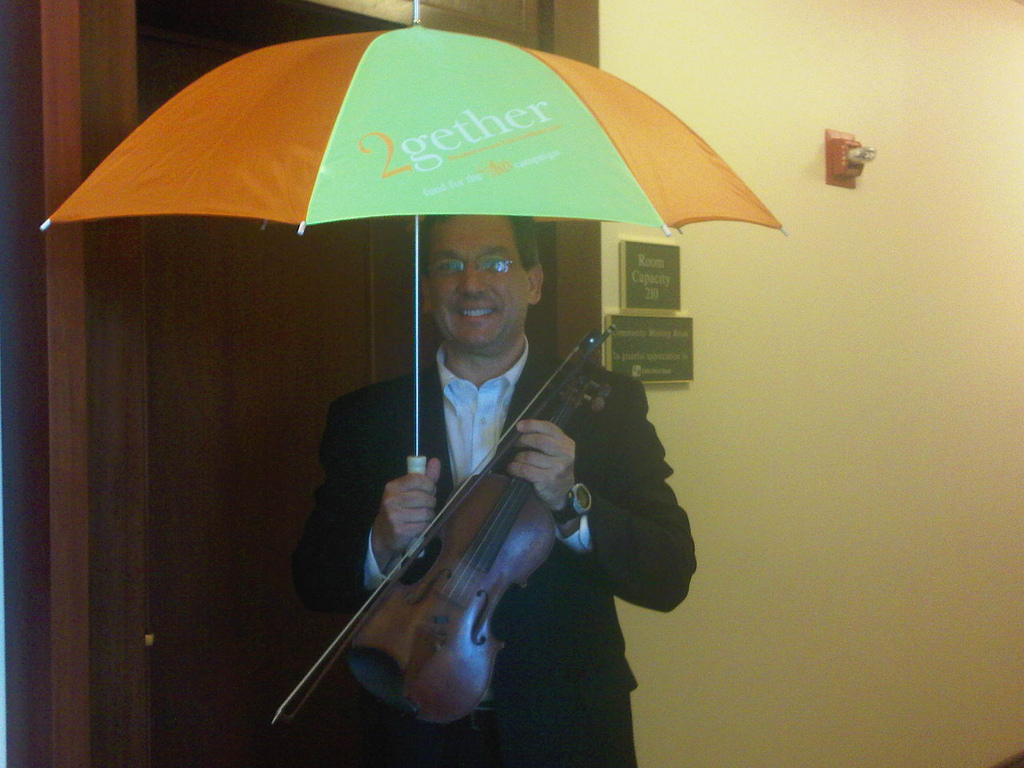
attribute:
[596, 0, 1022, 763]
wall — yellow 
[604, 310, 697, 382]
sign — black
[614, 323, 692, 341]
lettering — gold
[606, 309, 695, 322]
frame — gold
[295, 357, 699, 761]
jacket — black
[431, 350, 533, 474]
shirt — white 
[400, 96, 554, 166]
text — white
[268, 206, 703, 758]
man — posing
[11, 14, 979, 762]
building —  side 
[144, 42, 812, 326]
umbrella — green, orange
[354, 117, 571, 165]
letters — orange, white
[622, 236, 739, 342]
sign — black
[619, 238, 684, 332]
lettering — gold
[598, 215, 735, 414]
frame — gold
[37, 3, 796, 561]
umbrella —  tan,  Orange , open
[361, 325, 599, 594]
shirt — white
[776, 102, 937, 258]
fire alarm — red, clear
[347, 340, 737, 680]
violin — carved, wooden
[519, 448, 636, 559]
watch — black, grey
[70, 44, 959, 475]
umbrella — orange, light green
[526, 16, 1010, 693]
wall — beige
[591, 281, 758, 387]
plaque — black, gold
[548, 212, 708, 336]
plaque — gold, black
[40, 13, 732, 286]
umbrella — orange, green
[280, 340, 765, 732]
blazer — black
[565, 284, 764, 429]
placard — black, gold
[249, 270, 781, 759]
violin — brown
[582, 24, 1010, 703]
wall — yellow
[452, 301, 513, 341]
teeth — white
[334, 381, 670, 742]
violin — stringed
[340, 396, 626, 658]
violin — string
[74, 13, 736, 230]
umbrella — orange, green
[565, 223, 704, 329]
plate — black, square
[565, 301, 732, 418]
plate — black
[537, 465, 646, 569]
watch — white, black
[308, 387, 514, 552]
handle — white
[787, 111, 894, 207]
light — red, emergency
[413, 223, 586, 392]
face — smiling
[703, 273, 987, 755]
wall — cream, plain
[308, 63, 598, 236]
writings — orange, white